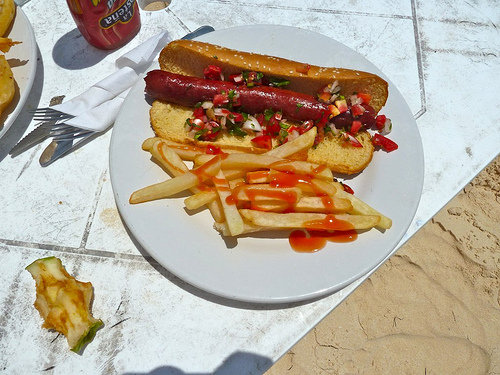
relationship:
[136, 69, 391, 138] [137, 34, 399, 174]
hot dog on bun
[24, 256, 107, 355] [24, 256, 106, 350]
apple core of apple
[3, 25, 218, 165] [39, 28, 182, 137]
forks rolled up in napkin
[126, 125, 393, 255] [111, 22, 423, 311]
food on plate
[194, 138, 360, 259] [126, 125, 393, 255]
ketchup on food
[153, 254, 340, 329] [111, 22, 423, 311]
edge of plate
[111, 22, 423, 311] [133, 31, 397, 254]
plate for food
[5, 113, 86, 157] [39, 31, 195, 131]
knife wrapped in napkin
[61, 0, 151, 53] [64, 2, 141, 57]
half of bottle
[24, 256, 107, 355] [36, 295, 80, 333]
apple core turning brown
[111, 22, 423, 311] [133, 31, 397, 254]
plate of food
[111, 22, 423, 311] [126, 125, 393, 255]
plate with food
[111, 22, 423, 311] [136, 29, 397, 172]
plate with hotdog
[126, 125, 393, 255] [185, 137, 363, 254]
food with ketchup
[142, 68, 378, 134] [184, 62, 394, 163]
hot dog with fixings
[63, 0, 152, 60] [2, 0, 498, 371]
ketchup on table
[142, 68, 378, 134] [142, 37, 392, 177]
hot dog in bun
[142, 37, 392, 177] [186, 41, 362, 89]
bun with sesame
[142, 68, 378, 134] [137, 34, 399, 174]
hot dog in bun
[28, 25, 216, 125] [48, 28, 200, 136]
forks in napkin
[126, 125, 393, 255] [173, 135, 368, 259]
food has ketchup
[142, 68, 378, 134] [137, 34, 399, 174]
hot dog on bun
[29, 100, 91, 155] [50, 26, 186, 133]
fork in paper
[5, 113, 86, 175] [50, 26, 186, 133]
knife in paper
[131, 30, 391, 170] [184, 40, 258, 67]
bun has sesame seeds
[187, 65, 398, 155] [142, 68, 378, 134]
pico de-gallo on hot dog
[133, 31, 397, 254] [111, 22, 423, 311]
food on plate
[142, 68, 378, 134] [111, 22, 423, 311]
hot dog on plate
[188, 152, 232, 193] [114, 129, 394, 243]
ketchup on french fries